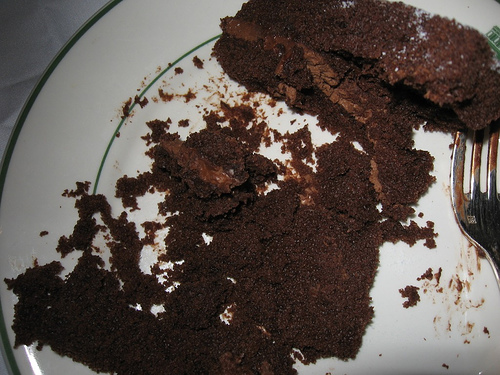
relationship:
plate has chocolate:
[0, 0, 499, 375] [97, 25, 352, 309]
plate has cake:
[0, 0, 499, 375] [44, 2, 489, 373]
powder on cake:
[407, 9, 430, 48] [0, 0, 499, 375]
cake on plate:
[0, 0, 499, 375] [0, 0, 499, 375]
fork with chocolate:
[452, 127, 498, 284] [87, 68, 429, 372]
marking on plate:
[94, 102, 144, 168] [8, 15, 223, 257]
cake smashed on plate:
[0, 0, 499, 375] [0, 0, 499, 375]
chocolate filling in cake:
[254, 230, 295, 306] [173, 66, 392, 373]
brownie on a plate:
[0, 0, 495, 371] [17, 102, 112, 172]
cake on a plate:
[139, 70, 346, 352] [43, 20, 498, 339]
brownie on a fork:
[100, 28, 413, 348] [426, 101, 498, 264]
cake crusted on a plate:
[0, 0, 499, 375] [0, 0, 499, 375]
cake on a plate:
[0, 0, 499, 375] [0, 0, 499, 375]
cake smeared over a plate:
[0, 0, 499, 375] [79, 66, 489, 363]